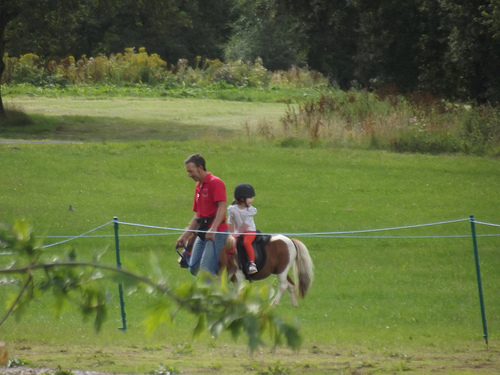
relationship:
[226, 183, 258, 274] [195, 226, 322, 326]
girl on pony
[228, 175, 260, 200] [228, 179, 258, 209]
helmet on head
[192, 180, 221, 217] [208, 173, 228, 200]
shirt with sleeves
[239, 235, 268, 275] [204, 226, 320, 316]
saddle on pony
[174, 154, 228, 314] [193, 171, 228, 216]
man wearing shirt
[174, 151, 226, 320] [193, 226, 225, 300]
man wearing jeans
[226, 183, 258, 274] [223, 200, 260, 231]
girl wearing shirt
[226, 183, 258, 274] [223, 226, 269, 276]
girl wearing leggings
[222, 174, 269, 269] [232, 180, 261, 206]
girl wearing helmet